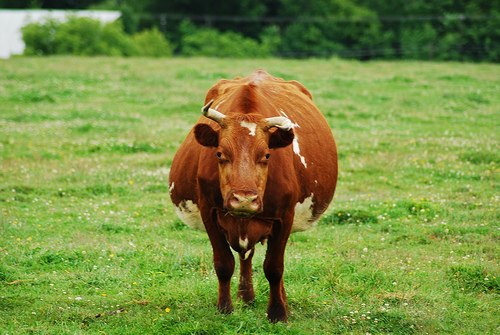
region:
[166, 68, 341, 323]
brown and white cow on a grassy field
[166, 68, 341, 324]
brown cow with white spots on it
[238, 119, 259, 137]
white spot on cows head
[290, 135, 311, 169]
white spot on a cow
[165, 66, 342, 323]
bloated brown and white cow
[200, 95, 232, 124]
horn on a cow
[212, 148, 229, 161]
eye of a cow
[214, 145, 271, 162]
eyes on a cow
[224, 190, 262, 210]
white nose of a cow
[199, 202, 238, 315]
leg of a cow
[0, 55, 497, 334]
the lush green grass on the ground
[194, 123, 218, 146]
the ear on the cow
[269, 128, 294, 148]
the ear on the cow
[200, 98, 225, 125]
the horn on the cow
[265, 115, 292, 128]
the horn on the cow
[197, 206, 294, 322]
the legs on the cow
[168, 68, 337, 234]
the widest area of the cow's body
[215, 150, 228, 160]
the eye on the cow's face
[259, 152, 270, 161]
the eye on the cow's face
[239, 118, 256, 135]
the white spot on the cow's head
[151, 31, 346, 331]
Bull walking in the field.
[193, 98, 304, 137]
The horns of a bull.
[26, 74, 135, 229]
Grass growing on the ground.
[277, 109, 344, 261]
Spots on a bull.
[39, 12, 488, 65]
Grass growing in the background.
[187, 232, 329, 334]
Legs of a bull.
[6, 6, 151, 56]
Fence in the distance.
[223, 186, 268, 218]
Snout of a bull.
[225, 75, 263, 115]
Large hump on bull's back.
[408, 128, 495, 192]
Flowers growing in the grass.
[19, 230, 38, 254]
yellow flower on ground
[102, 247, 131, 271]
yellow flower on ground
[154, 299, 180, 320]
yellow flower on ground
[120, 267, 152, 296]
yellow flower on ground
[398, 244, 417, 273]
yellow flower on ground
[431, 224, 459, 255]
yellow flower on ground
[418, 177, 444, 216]
yellow flower on ground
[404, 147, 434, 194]
yellow flower on ground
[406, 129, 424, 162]
yellow flower on ground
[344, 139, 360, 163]
yellow flower on ground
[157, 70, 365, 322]
brown and white cow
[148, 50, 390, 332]
cow standing on grass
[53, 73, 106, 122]
white flowers on grass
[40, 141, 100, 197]
white flowers on grass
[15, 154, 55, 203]
white flowers on grass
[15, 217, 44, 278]
white flowers on grass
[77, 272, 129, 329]
white flowers on grass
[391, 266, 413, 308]
white flowers on grass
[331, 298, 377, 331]
white flowers on grass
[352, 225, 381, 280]
white flowers on grass